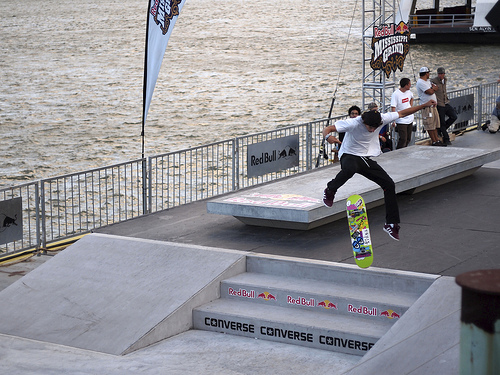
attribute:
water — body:
[3, 0, 487, 261]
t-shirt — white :
[331, 110, 398, 161]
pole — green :
[455, 267, 498, 371]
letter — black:
[202, 313, 356, 359]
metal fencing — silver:
[0, 77, 499, 264]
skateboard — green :
[345, 194, 372, 268]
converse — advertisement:
[201, 316, 256, 336]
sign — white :
[239, 130, 309, 180]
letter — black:
[201, 315, 255, 337]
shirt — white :
[392, 90, 420, 121]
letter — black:
[203, 316, 210, 325]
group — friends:
[327, 61, 464, 146]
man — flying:
[324, 103, 437, 245]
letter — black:
[196, 299, 213, 335]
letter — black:
[248, 322, 255, 336]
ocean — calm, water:
[0, 2, 378, 254]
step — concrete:
[206, 310, 411, 372]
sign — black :
[366, 19, 414, 74]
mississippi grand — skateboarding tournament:
[372, 27, 417, 67]